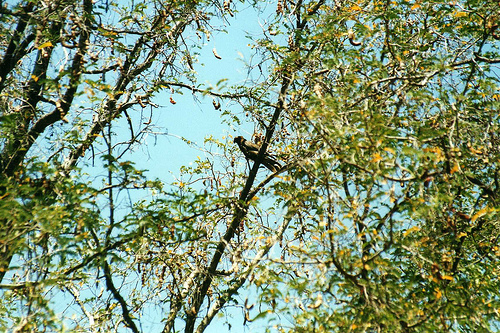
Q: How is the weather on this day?
A: It is cloudy.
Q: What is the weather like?
A: It is cloudy.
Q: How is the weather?
A: It is cloudy.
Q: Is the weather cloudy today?
A: Yes, it is cloudy.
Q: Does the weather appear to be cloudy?
A: Yes, it is cloudy.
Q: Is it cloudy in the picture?
A: Yes, it is cloudy.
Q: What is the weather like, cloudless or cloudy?
A: It is cloudy.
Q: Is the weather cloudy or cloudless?
A: It is cloudy.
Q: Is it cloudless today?
A: No, it is cloudy.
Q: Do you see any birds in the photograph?
A: Yes, there is a bird.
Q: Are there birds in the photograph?
A: Yes, there is a bird.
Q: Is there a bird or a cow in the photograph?
A: Yes, there is a bird.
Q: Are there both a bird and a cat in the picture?
A: No, there is a bird but no cats.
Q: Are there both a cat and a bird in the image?
A: No, there is a bird but no cats.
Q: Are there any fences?
A: No, there are no fences.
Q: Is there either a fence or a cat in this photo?
A: No, there are no fences or cats.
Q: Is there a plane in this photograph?
A: No, there are no airplanes.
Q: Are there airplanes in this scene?
A: No, there are no airplanes.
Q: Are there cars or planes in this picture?
A: No, there are no planes or cars.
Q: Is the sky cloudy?
A: Yes, the sky is cloudy.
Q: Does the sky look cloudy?
A: Yes, the sky is cloudy.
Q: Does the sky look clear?
A: No, the sky is cloudy.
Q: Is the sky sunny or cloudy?
A: The sky is cloudy.